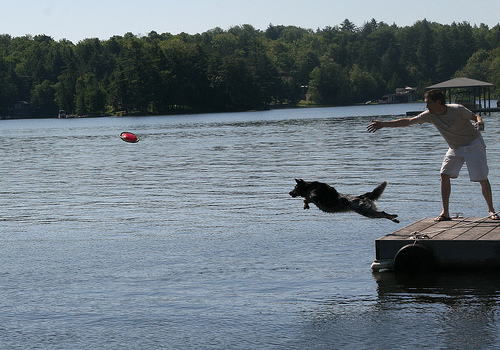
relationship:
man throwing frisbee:
[366, 89, 499, 222] [119, 130, 139, 144]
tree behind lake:
[339, 18, 355, 33] [0, 99, 498, 350]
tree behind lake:
[73, 76, 87, 120] [0, 99, 498, 350]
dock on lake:
[371, 216, 499, 272] [0, 99, 498, 350]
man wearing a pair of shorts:
[366, 89, 499, 222] [438, 135, 490, 183]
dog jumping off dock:
[288, 178, 401, 224] [371, 216, 499, 272]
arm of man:
[366, 111, 428, 138] [366, 89, 499, 222]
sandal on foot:
[434, 219, 450, 223] [433, 209, 451, 222]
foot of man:
[488, 210, 499, 220] [366, 89, 499, 222]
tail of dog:
[363, 180, 387, 201] [288, 178, 401, 224]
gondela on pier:
[429, 78, 493, 109] [470, 106, 499, 114]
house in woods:
[381, 86, 420, 105] [1, 18, 499, 121]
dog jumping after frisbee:
[288, 178, 401, 224] [119, 130, 139, 144]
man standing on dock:
[366, 89, 499, 222] [371, 216, 499, 272]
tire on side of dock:
[393, 243, 436, 278] [371, 216, 499, 272]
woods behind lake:
[1, 18, 499, 121] [0, 99, 498, 350]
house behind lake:
[381, 86, 420, 105] [0, 99, 498, 350]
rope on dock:
[410, 212, 499, 239] [371, 216, 499, 272]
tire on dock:
[393, 243, 436, 278] [371, 216, 499, 272]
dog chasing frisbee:
[288, 178, 401, 224] [119, 130, 139, 144]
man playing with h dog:
[366, 89, 499, 222] [288, 178, 401, 224]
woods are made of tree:
[1, 18, 499, 121] [339, 18, 355, 33]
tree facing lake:
[271, 75, 287, 105] [0, 99, 498, 350]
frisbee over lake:
[119, 130, 139, 144] [0, 99, 498, 350]